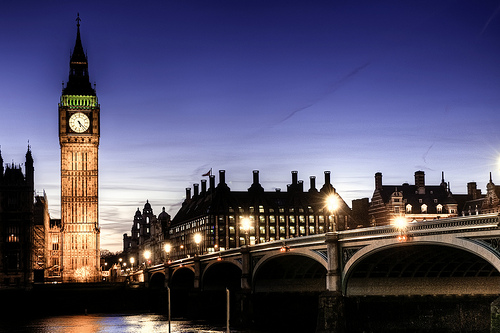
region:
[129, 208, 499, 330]
bridge going over the water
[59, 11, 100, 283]
large tower lit up at night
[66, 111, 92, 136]
giant clock on the top of the tower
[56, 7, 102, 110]
green roof on the tower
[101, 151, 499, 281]
lights going along the bridge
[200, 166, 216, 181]
flag on the top of the building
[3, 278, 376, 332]
calm body of water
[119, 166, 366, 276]
building with many windows by the road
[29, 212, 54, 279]
stair case going up the side of the building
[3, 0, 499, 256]
cloudless sky at dusk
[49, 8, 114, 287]
A light up tower with a clock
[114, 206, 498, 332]
A bridge with light all along it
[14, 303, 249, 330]
part of a river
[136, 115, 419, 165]
Part of the sky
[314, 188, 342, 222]
A light on, on a bridge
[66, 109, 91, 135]
a light up clock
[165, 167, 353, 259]
a building with a lot of windows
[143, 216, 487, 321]
A bridge with arches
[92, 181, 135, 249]
Whispy clounds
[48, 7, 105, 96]
The top of a tower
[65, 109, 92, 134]
A clock in a tower.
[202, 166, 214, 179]
A flag on top of a building.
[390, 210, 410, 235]
A bright light on a bridge.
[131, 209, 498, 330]
A bridge over the water.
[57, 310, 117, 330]
Reflection of the tower.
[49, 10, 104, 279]
A clock tower over looking the water.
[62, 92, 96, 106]
Neon green lights lighting up the tower.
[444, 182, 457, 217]
A turret on a building.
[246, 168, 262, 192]
A chimney on top of a building.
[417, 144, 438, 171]
Smoke billowing out of a chimney.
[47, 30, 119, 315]
Large clock tower that is lit up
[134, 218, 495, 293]
Bridge with arches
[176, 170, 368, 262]
Building with many lit up windows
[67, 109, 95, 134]
white and black lit up clock face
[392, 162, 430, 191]
Brick chimney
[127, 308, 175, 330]
Reflection of the lights in the water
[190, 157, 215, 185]
Flag flying int he wind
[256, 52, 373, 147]
Faint airplane trail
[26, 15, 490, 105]
Dark blue evening sky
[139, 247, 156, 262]
Light attached to the bridge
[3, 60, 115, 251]
a tallclock tower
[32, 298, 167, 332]
lights reflected on the water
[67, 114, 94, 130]
black and white clock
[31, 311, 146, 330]
red white and blue lights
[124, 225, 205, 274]
four white globe lights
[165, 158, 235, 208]
flag on top of roof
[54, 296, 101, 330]
red light on water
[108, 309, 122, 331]
blue light on water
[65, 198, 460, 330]
a bridge over water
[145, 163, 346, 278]
building with lots of windows